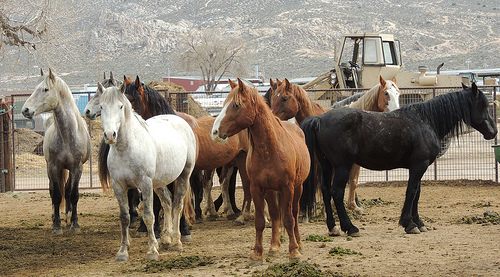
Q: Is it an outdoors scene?
A: Yes, it is outdoors.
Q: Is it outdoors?
A: Yes, it is outdoors.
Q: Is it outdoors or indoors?
A: It is outdoors.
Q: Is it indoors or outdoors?
A: It is outdoors.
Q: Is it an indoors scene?
A: No, it is outdoors.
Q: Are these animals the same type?
A: Yes, all the animals are horses.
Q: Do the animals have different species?
A: No, all the animals are horses.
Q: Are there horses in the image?
A: Yes, there is a horse.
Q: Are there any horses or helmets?
A: Yes, there is a horse.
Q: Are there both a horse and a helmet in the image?
A: No, there is a horse but no helmets.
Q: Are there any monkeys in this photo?
A: No, there are no monkeys.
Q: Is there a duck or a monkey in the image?
A: No, there are no monkeys or ducks.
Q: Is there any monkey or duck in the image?
A: No, there are no monkeys or ducks.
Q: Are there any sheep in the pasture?
A: No, there is a horse in the pasture.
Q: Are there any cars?
A: No, there are no cars.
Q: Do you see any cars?
A: No, there are no cars.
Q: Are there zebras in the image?
A: No, there are no zebras.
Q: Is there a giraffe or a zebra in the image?
A: No, there are no zebras or giraffes.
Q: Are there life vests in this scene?
A: No, there are no life vests.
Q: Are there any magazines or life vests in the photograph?
A: No, there are no life vests or magazines.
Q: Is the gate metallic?
A: Yes, the gate is metallic.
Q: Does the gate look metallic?
A: Yes, the gate is metallic.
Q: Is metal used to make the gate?
A: Yes, the gate is made of metal.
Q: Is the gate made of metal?
A: Yes, the gate is made of metal.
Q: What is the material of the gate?
A: The gate is made of metal.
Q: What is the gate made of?
A: The gate is made of metal.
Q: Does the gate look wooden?
A: No, the gate is metallic.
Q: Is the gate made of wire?
A: No, the gate is made of metal.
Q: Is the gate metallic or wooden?
A: The gate is metallic.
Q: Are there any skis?
A: No, there are no skis.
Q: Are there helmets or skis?
A: No, there are no skis or helmets.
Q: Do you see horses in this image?
A: Yes, there is a horse.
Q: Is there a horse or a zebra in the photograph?
A: Yes, there is a horse.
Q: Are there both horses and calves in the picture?
A: No, there is a horse but no calves.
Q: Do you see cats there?
A: No, there are no cats.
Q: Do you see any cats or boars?
A: No, there are no cats or boars.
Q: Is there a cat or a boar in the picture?
A: No, there are no cats or boars.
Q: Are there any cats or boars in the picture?
A: No, there are no cats or boars.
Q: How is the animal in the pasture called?
A: The animal is a horse.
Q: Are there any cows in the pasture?
A: No, there is a horse in the pasture.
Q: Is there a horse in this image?
A: Yes, there is a horse.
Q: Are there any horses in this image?
A: Yes, there is a horse.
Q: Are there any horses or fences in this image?
A: Yes, there is a horse.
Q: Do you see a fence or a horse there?
A: Yes, there is a horse.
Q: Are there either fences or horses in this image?
A: Yes, there is a horse.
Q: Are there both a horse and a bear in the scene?
A: No, there is a horse but no bears.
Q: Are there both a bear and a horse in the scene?
A: No, there is a horse but no bears.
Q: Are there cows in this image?
A: No, there are no cows.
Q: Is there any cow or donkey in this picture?
A: No, there are no cows or donkeys.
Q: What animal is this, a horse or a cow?
A: This is a horse.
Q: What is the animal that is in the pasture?
A: The animal is a horse.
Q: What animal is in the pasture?
A: The animal is a horse.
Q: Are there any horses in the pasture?
A: Yes, there is a horse in the pasture.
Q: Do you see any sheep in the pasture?
A: No, there is a horse in the pasture.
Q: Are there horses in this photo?
A: Yes, there is a horse.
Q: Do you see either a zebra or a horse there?
A: Yes, there is a horse.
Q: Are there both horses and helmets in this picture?
A: No, there is a horse but no helmets.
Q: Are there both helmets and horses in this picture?
A: No, there is a horse but no helmets.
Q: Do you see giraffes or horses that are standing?
A: Yes, the horse is standing.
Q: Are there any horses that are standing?
A: Yes, there is a horse that is standing.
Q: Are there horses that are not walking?
A: Yes, there is a horse that is standing.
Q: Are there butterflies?
A: No, there are no butterflies.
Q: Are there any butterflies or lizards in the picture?
A: No, there are no butterflies or lizards.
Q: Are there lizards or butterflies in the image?
A: No, there are no butterflies or lizards.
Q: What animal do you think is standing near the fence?
A: The horse is standing near the fence.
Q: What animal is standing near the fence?
A: The horse is standing near the fence.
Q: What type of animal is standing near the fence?
A: The animal is a horse.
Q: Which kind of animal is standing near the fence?
A: The animal is a horse.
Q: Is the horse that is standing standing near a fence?
A: Yes, the horse is standing near a fence.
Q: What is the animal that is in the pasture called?
A: The animal is a horse.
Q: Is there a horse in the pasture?
A: Yes, there is a horse in the pasture.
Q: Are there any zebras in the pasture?
A: No, there is a horse in the pasture.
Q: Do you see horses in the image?
A: Yes, there is a horse.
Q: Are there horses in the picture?
A: Yes, there is a horse.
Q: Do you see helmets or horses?
A: Yes, there is a horse.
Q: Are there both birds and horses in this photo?
A: No, there is a horse but no birds.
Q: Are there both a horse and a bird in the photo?
A: No, there is a horse but no birds.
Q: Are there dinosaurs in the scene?
A: No, there are no dinosaurs.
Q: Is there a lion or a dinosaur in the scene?
A: No, there are no dinosaurs or lions.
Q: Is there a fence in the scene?
A: Yes, there is a fence.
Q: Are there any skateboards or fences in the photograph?
A: Yes, there is a fence.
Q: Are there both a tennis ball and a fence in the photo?
A: No, there is a fence but no tennis balls.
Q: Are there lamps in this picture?
A: No, there are no lamps.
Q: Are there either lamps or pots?
A: No, there are no lamps or pots.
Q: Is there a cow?
A: No, there are no cows.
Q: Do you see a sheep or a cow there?
A: No, there are no cows or sheep.